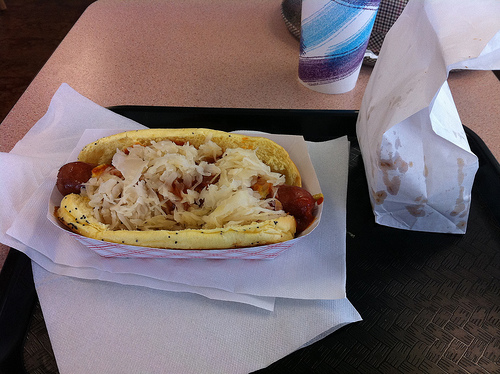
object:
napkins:
[28, 257, 362, 373]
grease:
[403, 203, 426, 218]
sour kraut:
[218, 145, 286, 185]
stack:
[0, 221, 352, 374]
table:
[0, 0, 499, 373]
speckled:
[24, 83, 47, 114]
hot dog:
[53, 126, 318, 249]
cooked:
[111, 148, 146, 196]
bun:
[54, 125, 300, 250]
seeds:
[131, 238, 139, 243]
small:
[89, 340, 119, 363]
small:
[168, 104, 208, 115]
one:
[120, 157, 133, 168]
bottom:
[296, 60, 360, 93]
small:
[368, 284, 390, 312]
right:
[274, 187, 316, 222]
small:
[13, 50, 21, 54]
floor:
[0, 0, 93, 121]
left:
[56, 160, 90, 196]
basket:
[44, 128, 323, 263]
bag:
[354, 0, 499, 236]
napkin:
[4, 125, 346, 302]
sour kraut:
[193, 162, 209, 178]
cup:
[296, 0, 381, 96]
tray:
[0, 105, 499, 374]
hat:
[279, 0, 405, 69]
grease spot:
[393, 152, 408, 176]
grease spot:
[379, 168, 399, 197]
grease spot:
[452, 156, 466, 190]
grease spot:
[456, 213, 467, 220]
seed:
[271, 219, 278, 223]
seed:
[172, 239, 181, 245]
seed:
[166, 233, 174, 239]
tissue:
[0, 83, 279, 314]